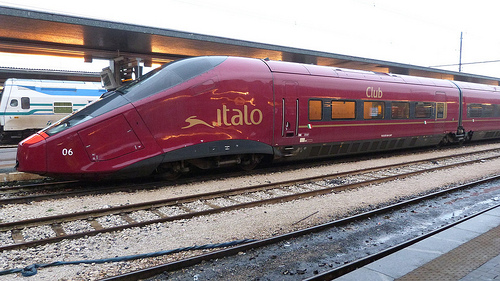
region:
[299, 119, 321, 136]
white spot on side of the train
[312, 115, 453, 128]
gold line running down side of train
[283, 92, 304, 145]
door on side of train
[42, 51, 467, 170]
purple bullet train on track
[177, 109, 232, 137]
small gold animal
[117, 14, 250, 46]
gray color on top of track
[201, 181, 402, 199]
long train tracks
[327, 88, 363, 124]
gold windows on side of train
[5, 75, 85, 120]
blue and white camper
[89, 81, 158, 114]
window on front of train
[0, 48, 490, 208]
a bullet train on the tracks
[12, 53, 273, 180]
the train engine is red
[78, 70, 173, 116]
windshield wipers are on the engine windows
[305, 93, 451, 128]
the windows on a passenger car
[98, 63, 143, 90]
information screens are on the platform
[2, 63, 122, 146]
a train is on the next tracks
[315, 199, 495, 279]
an empty platform next to the tracks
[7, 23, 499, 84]
ceiling lights are on the platform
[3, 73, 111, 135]
the train is silver and blue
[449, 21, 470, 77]
a pole with wires is in the background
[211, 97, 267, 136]
italo writing on train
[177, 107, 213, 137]
Symbol on side of train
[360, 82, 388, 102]
Club writing on side of train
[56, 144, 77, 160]
06 Number on train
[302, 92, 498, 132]
Side windows on train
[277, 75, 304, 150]
Door on side of train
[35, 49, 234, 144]
Window on maroon train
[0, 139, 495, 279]
Sets of railroad tracks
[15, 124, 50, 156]
Light on maroon train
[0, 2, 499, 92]
Overhang at train station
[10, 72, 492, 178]
sleek maroon train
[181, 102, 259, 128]
train label written in gold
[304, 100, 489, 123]
row of windows on the train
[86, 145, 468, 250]
train tracks and pebbles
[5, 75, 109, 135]
white and aqua train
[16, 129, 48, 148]
red nose of a train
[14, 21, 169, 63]
lights underneath a roof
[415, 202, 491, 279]
cement platform near the tracks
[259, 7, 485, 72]
bright white sky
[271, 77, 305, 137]
door of the train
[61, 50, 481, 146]
red train on track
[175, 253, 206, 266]
metal side of track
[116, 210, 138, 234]
cross tie of railroad track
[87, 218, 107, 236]
cross tie of railroad track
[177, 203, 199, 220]
cross tie of railroad track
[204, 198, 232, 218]
cross tie of railroad track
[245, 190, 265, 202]
cross tie of railroad track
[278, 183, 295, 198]
cross tie of railroad track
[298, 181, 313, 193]
cross tie of railroad track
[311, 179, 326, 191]
cross tie of railroad track